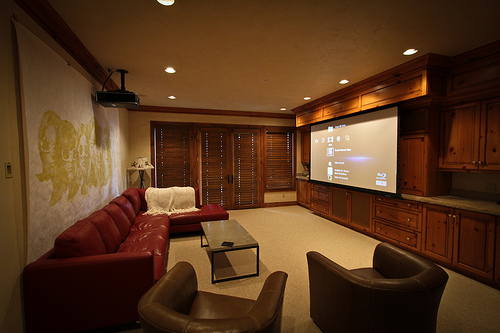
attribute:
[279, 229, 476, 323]
chair — brown 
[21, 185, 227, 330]
sofa — Long red leather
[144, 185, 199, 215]
blanket — White 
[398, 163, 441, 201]
ground — red, leather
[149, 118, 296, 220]
windows — Brown wooden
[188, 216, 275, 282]
table — glass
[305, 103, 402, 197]
projector screen — large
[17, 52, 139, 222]
animals — yellow 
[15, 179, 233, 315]
sofa — Red leather setional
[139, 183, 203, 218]
throw blanket — white throw 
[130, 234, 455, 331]
chairs — Two brown leather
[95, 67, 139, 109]
projector — Black 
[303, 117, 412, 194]
screen — white projection, Black 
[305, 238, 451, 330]
seat — leather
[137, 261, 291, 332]
seat — leather, brown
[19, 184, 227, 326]
seat — leather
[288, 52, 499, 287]
cabinets — wooden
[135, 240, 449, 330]
arm chairs — brown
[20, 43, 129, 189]
art — white, Gold 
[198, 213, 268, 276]
coffee table — granite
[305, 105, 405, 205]
tv screen — large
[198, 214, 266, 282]
coffee table — Black , Grey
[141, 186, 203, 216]
blanket — white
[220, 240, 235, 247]
remote —  control 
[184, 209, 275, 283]
table — tan and black, coffee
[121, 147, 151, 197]
lamp — tall, black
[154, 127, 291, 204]
blinds — wooden, closed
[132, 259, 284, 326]
seat — curved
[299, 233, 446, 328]
chair — brown, leather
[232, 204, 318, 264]
floor — carpeted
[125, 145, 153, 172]
shade — White lamp 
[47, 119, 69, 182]
tapestry — large white 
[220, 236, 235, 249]
control — small black remote 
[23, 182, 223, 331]
couch —  red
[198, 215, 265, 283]
table — brown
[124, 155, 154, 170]
lamp shade — white